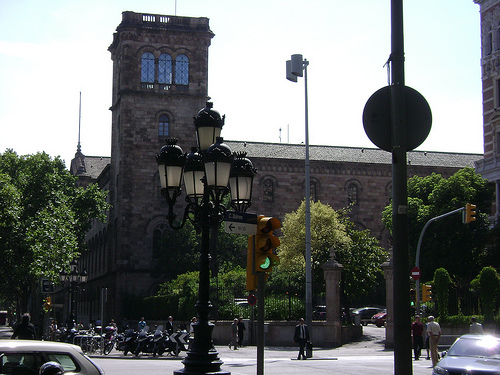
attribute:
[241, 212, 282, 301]
stoplight — metal, yellow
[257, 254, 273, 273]
light — on, green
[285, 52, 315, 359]
light pole — metal, silver, cast, tall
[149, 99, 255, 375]
light pole — decorative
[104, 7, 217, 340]
building — tower, brick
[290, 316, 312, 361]
man — pedestrian, walking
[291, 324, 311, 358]
suit — black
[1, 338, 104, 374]
car — parked, cream, white, turning left, light colored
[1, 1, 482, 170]
sky — white, hazy, cloudy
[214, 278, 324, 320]
fence — black, iron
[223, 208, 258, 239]
street sign — black, white, two toned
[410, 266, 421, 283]
road sign — red, white, no entry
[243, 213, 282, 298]
traffic light — modern, short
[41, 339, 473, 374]
street — attractive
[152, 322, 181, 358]
motorcycle — parked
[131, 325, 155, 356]
motorcycle — parked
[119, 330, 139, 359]
motorcycle — parked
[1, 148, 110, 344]
tree — growing, full, green, tall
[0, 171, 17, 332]
tree — growing, green, tall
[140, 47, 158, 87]
window — large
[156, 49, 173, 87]
window — large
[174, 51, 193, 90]
window — large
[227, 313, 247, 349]
couple — pedestrians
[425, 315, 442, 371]
man — pedestrian, walking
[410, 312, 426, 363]
man — pedestrian, walking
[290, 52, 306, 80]
light — covered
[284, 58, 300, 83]
light — covered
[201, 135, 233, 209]
light — covered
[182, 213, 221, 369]
light post — metal, black, old-fashioned, structural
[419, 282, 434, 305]
stoplight — yellow, metal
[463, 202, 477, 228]
stoplight — yellow, metal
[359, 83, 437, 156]
sign — grey, circular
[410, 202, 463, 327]
pole — overhanging, long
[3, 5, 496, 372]
scene — attractive, summery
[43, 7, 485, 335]
church — stone, elderly